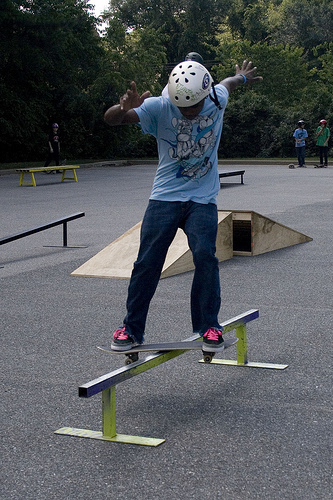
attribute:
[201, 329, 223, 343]
strings — pink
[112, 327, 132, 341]
strings — pink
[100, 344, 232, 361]
skateboard — black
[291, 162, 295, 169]
skateboard — black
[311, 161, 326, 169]
skateboard — black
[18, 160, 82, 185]
skateboardjump — long, yellow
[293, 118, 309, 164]
man — young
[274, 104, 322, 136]
people — talking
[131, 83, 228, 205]
t-shirt — blue, round-neck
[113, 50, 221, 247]
person — watching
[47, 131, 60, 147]
shirt — black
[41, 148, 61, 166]
pants — black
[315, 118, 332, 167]
person — safety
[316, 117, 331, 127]
helmet — red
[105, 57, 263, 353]
man — young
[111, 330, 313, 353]
tennis shoes — black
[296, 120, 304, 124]
safety helmet — black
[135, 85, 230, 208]
shirt — blue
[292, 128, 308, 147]
shirt — blue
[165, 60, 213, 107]
helmet — safety, white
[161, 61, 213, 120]
head — person's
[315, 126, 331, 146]
t-shirt — green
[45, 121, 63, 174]
man — young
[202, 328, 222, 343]
shoelaces — pink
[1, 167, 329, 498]
ground — pictured